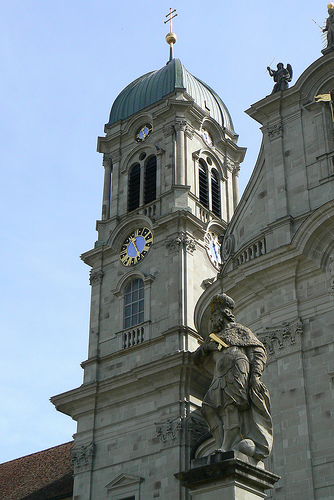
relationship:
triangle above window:
[129, 142, 150, 160] [125, 160, 176, 201]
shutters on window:
[103, 168, 148, 190] [125, 160, 176, 201]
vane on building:
[162, 9, 187, 27] [25, 6, 323, 481]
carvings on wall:
[244, 247, 283, 272] [10, 468, 55, 483]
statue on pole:
[265, 45, 296, 92] [158, 47, 160, 48]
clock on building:
[121, 228, 155, 261] [25, 6, 323, 481]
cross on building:
[233, 247, 260, 259] [25, 6, 323, 481]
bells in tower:
[262, 127, 263, 128] [316, 66, 324, 83]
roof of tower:
[111, 72, 168, 99] [316, 66, 324, 83]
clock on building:
[121, 228, 155, 261] [49, 55, 330, 497]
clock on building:
[121, 228, 155, 261] [51, 56, 277, 498]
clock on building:
[121, 228, 155, 261] [49, 52, 246, 497]